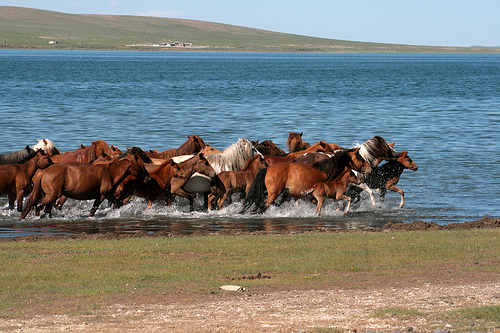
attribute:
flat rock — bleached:
[220, 282, 244, 290]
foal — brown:
[299, 165, 360, 220]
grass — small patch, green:
[0, 231, 496, 293]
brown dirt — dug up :
[223, 265, 277, 294]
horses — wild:
[2, 129, 432, 226]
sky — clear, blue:
[0, 1, 500, 47]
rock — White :
[219, 282, 242, 290]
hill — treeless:
[2, 3, 497, 53]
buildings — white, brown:
[130, 34, 207, 54]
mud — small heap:
[2, 214, 499, 243]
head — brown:
[364, 131, 401, 160]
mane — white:
[354, 137, 381, 169]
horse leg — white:
[367, 164, 404, 218]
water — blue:
[27, 30, 476, 234]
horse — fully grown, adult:
[242, 147, 369, 217]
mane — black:
[311, 147, 356, 183]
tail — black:
[239, 165, 266, 216]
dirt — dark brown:
[0, 215, 498, 242]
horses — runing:
[56, 144, 423, 229]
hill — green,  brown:
[2, 7, 306, 52]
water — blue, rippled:
[0, 46, 499, 237]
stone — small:
[217, 282, 246, 292]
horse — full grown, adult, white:
[169, 137, 268, 209]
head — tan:
[190, 139, 232, 165]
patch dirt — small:
[206, 288, 447, 331]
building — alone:
[45, 37, 62, 50]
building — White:
[47, 38, 56, 45]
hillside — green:
[0, 0, 499, 50]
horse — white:
[204, 136, 260, 171]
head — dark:
[29, 144, 48, 165]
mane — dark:
[7, 147, 40, 163]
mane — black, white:
[358, 134, 397, 167]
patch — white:
[1, 282, 497, 331]